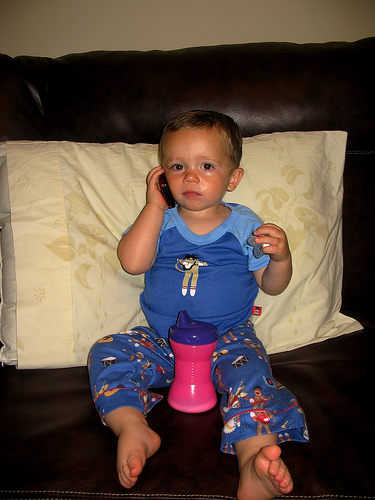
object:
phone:
[158, 173, 176, 209]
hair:
[156, 109, 243, 170]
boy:
[87, 120, 291, 498]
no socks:
[104, 404, 161, 489]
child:
[87, 108, 309, 498]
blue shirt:
[166, 218, 250, 319]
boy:
[117, 110, 292, 472]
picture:
[244, 338, 268, 363]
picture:
[0, 0, 375, 500]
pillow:
[0, 131, 363, 370]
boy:
[75, 94, 318, 485]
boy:
[102, 118, 342, 483]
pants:
[86, 318, 310, 455]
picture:
[175, 253, 209, 297]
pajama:
[87, 199, 310, 456]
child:
[87, 108, 301, 499]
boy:
[85, 109, 309, 497]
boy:
[153, 114, 224, 228]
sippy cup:
[168, 309, 219, 413]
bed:
[10, 43, 372, 497]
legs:
[209, 318, 309, 499]